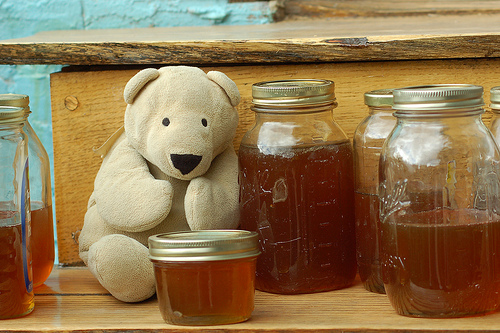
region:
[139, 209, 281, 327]
a small jar of honey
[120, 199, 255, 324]
honey with a silver lid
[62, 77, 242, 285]
a small white teddy bear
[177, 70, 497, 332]
five jars of honey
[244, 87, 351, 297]
jar almost full of honey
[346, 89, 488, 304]
jar half full of honey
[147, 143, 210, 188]
black nose of stuffed bear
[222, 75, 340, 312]
mason jar with measurment on it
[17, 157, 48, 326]
label on a honey jar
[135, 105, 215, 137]
two black eyes of stuffed animal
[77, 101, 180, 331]
a stuffed toy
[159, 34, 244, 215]
a stuffed toy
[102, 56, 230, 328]
a stuffed toy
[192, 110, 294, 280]
a stuffed toy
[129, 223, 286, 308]
small mason jar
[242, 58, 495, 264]
four large mason jars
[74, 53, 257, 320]
bear is a tan color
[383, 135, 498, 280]
mason jar is half full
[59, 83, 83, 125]
nail in the board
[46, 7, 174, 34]
wall is a aqua color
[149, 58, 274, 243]
bear is leaning on mason jar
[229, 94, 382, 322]
mason jar is full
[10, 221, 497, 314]
mason jar sitting on wood boards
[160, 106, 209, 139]
bear has small black eyes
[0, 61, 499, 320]
seven jars of honey, an inanimate, if lively looking, bear among them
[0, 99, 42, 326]
this jar of honey may be capless, has blue bordered label, & is about 3/5 full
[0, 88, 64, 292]
the jar of honey behind it has a cap, has no visible label, is also about 3/5 full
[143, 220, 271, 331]
a much smaller full jar of honey; bear looks to be preparing to use it as a lone bongo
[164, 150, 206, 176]
bears nose is a sewn+blunted black triangle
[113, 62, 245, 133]
bear has two black button eyes, two cooky curly annular ears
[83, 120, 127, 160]
bear may still have attached tag at bear's right back neck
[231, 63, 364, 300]
this jar of honey is a ball [home canning] jar; it's about ? full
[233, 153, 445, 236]
the logo 'ball' in cursive, in+on glass, on previous jar & jar two doors down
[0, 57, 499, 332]
all of the honey caps are goldtone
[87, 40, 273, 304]
Teddy bear sitting on shelf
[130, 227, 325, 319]
Small container of honey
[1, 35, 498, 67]
Wooden bark shelf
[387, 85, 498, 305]
Honey jar that is half full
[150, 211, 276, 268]
Metal lid on container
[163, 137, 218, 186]
Black nose on bear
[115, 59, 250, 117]
Ears on top of bear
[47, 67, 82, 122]
wooden back of the shelf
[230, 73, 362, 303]
Almost full jar of honey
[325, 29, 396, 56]
Small knot in shelf